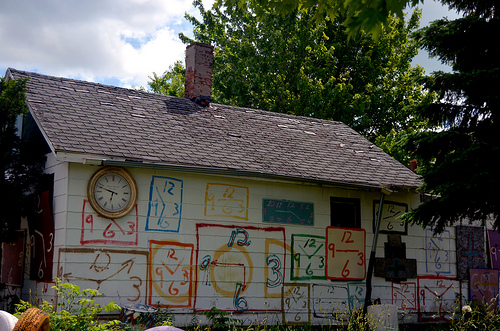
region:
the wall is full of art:
[179, 237, 379, 322]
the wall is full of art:
[190, 194, 328, 304]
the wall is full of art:
[199, 194, 290, 275]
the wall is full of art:
[229, 221, 316, 279]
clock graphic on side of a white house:
[86, 169, 137, 218]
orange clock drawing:
[148, 236, 195, 309]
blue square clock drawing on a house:
[141, 173, 187, 234]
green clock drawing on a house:
[289, 233, 331, 278]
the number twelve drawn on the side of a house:
[156, 179, 179, 196]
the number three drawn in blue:
[169, 197, 184, 215]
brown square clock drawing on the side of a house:
[56, 244, 152, 309]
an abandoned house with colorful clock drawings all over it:
[6, 43, 498, 327]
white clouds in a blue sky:
[1, 3, 188, 85]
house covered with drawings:
[35, 47, 433, 329]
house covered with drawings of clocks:
[72, 170, 392, 281]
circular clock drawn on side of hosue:
[77, 164, 148, 239]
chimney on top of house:
[174, 28, 236, 126]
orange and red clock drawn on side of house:
[90, 230, 214, 314]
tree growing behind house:
[68, 7, 418, 175]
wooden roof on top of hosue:
[30, 104, 370, 221]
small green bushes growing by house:
[15, 250, 147, 330]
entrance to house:
[5, 121, 69, 325]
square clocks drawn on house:
[134, 178, 216, 329]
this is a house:
[65, 112, 324, 305]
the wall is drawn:
[182, 197, 334, 307]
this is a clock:
[81, 171, 144, 211]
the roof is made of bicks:
[252, 121, 327, 163]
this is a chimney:
[175, 37, 217, 105]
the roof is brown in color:
[77, 95, 152, 143]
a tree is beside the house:
[302, 10, 375, 85]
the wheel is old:
[17, 301, 47, 329]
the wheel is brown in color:
[15, 305, 47, 326]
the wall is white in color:
[54, 173, 79, 220]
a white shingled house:
[7, 37, 498, 320]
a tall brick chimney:
[178, 38, 221, 110]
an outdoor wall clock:
[82, 165, 137, 221]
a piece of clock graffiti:
[52, 247, 152, 314]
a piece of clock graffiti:
[143, 236, 195, 315]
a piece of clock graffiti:
[77, 197, 136, 249]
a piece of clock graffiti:
[143, 172, 185, 234]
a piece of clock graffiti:
[199, 179, 252, 223]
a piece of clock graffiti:
[192, 218, 285, 313]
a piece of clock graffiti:
[285, 229, 327, 282]